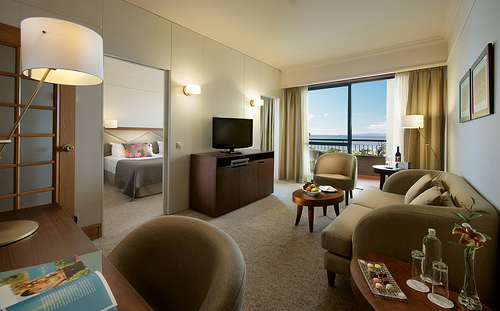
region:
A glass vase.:
[457, 259, 479, 307]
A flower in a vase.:
[449, 200, 490, 251]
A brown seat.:
[117, 212, 250, 306]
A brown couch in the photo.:
[364, 167, 476, 233]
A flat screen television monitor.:
[208, 112, 260, 156]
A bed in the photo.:
[106, 139, 163, 195]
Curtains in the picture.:
[278, 89, 306, 187]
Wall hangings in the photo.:
[461, 59, 498, 122]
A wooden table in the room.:
[37, 223, 79, 259]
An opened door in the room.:
[101, 65, 166, 232]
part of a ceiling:
[246, 2, 284, 42]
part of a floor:
[253, 238, 290, 290]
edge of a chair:
[205, 227, 248, 271]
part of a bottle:
[411, 221, 443, 265]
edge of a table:
[118, 271, 141, 293]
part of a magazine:
[68, 280, 89, 300]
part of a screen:
[218, 115, 260, 156]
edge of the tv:
[201, 97, 216, 152]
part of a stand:
[296, 201, 316, 245]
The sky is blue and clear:
[310, 90, 385, 146]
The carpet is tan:
[237, 218, 308, 293]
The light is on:
[12, 5, 118, 116]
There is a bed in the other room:
[105, 106, 187, 221]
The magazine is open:
[0, 220, 128, 308]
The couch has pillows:
[393, 163, 468, 251]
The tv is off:
[200, 105, 276, 170]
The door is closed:
[293, 75, 441, 187]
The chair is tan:
[303, 140, 366, 202]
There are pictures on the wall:
[451, 55, 498, 136]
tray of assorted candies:
[359, 259, 390, 309]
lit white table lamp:
[18, 15, 116, 102]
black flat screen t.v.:
[201, 108, 273, 165]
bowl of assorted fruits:
[298, 180, 321, 195]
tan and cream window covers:
[284, 90, 319, 187]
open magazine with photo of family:
[3, 267, 56, 307]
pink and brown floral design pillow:
[121, 140, 166, 177]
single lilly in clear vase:
[451, 217, 486, 309]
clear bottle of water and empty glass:
[423, 229, 447, 286]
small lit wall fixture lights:
[178, 70, 280, 129]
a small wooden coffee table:
[285, 177, 342, 232]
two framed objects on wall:
[447, 36, 493, 138]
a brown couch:
[330, 156, 496, 262]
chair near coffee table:
[292, 145, 357, 218]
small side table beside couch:
[325, 172, 491, 307]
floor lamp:
[393, 106, 449, 171]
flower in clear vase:
[443, 190, 490, 307]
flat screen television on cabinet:
[190, 108, 277, 218]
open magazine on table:
[0, 190, 142, 306]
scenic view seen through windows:
[278, 68, 423, 182]